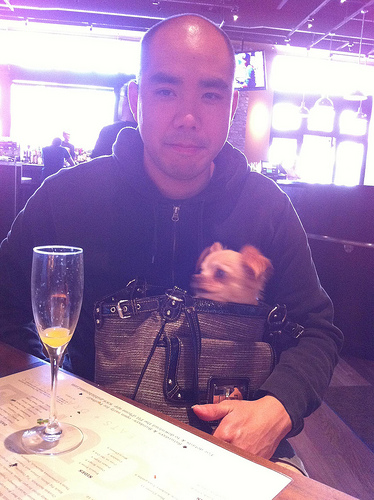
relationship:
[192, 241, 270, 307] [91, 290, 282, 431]
dog in a purse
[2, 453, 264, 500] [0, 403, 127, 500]
table has a menu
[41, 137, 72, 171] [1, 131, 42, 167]
man at bar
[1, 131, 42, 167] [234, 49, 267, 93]
bar has a television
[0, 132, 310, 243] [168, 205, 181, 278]
jacket has a zipper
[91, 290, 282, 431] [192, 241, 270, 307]
handbag carrying a puppy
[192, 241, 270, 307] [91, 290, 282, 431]
puppy held in a handbag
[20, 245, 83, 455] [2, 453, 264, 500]
champaigne flute on table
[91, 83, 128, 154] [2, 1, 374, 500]
people in restaurant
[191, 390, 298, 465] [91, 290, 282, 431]
mans left hand holding handbag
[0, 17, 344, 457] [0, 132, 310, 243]
man wearing a sweater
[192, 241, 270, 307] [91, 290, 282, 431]
dog in purse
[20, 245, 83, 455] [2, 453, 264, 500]
champaigne flute on table menu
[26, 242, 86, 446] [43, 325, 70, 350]
champaigne flute has a mimosa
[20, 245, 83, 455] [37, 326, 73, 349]
champaigne flute in glass orange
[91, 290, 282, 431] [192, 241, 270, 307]
bag has a puppy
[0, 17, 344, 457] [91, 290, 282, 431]
man holding handbag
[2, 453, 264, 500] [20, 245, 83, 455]
table has a champaigne flute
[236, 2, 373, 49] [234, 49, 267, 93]
ceiling has a tv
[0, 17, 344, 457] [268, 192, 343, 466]
man has a handbag in his arm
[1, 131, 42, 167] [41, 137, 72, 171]
bar serving people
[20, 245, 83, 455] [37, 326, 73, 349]
champaigne flute has orange juice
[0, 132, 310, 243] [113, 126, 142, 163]
jacket has a hood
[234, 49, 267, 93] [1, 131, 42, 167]
television over bar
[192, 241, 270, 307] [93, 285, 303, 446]
head sticking out of purse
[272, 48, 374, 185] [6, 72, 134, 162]
light glare coming through window